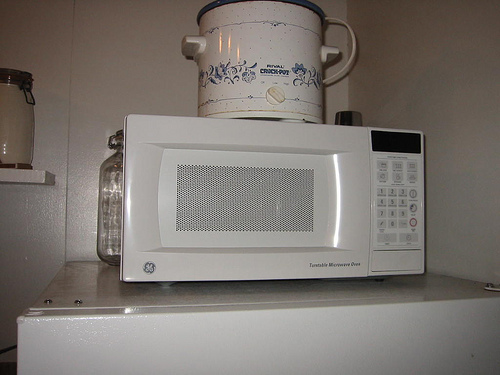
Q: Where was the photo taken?
A: It was taken at the kitchen.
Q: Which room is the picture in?
A: It is at the kitchen.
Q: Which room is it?
A: It is a kitchen.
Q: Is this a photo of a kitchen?
A: Yes, it is showing a kitchen.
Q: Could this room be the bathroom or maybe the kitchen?
A: It is the kitchen.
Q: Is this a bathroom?
A: No, it is a kitchen.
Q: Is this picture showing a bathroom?
A: No, the picture is showing a kitchen.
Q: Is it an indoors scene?
A: Yes, it is indoors.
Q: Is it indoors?
A: Yes, it is indoors.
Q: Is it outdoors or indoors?
A: It is indoors.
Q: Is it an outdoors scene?
A: No, it is indoors.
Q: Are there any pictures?
A: No, there are no pictures.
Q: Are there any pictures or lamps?
A: No, there are no pictures or lamps.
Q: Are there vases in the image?
A: No, there are no vases.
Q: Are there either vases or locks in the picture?
A: No, there are no vases or locks.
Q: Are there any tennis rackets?
A: No, there are no tennis rackets.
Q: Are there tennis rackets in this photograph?
A: No, there are no tennis rackets.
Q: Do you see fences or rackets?
A: No, there are no rackets or fences.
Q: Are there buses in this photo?
A: No, there are no buses.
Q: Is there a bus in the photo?
A: No, there are no buses.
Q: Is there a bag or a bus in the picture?
A: No, there are no buses or bags.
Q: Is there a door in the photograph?
A: Yes, there is a door.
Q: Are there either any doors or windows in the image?
A: Yes, there is a door.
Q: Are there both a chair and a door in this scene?
A: No, there is a door but no chairs.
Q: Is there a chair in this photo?
A: No, there are no chairs.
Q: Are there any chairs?
A: No, there are no chairs.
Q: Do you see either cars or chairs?
A: No, there are no chairs or cars.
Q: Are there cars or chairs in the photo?
A: No, there are no chairs or cars.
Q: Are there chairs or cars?
A: No, there are no chairs or cars.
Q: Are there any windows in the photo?
A: Yes, there is a window.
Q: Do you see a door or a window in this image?
A: Yes, there is a window.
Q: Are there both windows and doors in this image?
A: Yes, there are both a window and a door.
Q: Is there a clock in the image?
A: No, there are no clocks.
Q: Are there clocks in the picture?
A: No, there are no clocks.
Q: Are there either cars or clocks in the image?
A: No, there are no clocks or cars.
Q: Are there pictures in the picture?
A: No, there are no pictures.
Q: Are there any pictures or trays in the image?
A: No, there are no pictures or trays.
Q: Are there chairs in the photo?
A: No, there are no chairs.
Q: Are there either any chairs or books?
A: No, there are no chairs or books.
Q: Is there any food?
A: No, there is no food.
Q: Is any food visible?
A: No, there is no food.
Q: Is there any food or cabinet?
A: No, there are no food or cabinets.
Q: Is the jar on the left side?
A: Yes, the jar is on the left of the image.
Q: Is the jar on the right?
A: No, the jar is on the left of the image.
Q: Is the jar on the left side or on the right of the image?
A: The jar is on the left of the image.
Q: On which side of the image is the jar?
A: The jar is on the left of the image.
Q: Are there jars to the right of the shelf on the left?
A: Yes, there is a jar to the right of the shelf.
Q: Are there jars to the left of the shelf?
A: No, the jar is to the right of the shelf.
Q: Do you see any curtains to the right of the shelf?
A: No, there is a jar to the right of the shelf.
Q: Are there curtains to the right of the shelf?
A: No, there is a jar to the right of the shelf.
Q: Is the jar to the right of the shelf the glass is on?
A: Yes, the jar is to the right of the shelf.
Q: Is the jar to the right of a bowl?
A: No, the jar is to the right of the shelf.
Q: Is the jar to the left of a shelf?
A: No, the jar is to the right of a shelf.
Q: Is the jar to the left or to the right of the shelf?
A: The jar is to the right of the shelf.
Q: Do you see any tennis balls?
A: No, there are no tennis balls.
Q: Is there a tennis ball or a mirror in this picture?
A: No, there are no tennis balls or mirrors.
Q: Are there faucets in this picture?
A: No, there are no faucets.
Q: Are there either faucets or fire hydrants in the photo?
A: No, there are no faucets or fire hydrants.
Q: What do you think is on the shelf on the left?
A: The glass is on the shelf.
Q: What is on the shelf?
A: The glass is on the shelf.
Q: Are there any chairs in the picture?
A: No, there are no chairs.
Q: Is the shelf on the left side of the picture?
A: Yes, the shelf is on the left of the image.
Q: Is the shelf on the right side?
A: No, the shelf is on the left of the image.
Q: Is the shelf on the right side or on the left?
A: The shelf is on the left of the image.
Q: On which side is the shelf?
A: The shelf is on the left of the image.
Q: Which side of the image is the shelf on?
A: The shelf is on the left of the image.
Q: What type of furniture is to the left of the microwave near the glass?
A: The piece of furniture is a shelf.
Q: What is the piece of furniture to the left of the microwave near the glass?
A: The piece of furniture is a shelf.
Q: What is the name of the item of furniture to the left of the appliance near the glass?
A: The piece of furniture is a shelf.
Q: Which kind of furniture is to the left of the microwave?
A: The piece of furniture is a shelf.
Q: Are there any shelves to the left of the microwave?
A: Yes, there is a shelf to the left of the microwave.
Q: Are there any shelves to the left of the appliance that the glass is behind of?
A: Yes, there is a shelf to the left of the microwave.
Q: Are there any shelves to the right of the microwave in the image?
A: No, the shelf is to the left of the microwave.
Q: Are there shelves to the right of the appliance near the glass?
A: No, the shelf is to the left of the microwave.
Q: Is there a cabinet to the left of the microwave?
A: No, there is a shelf to the left of the microwave.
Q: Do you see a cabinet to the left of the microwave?
A: No, there is a shelf to the left of the microwave.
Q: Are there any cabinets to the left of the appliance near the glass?
A: No, there is a shelf to the left of the microwave.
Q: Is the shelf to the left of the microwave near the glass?
A: Yes, the shelf is to the left of the microwave.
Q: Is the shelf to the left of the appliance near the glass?
A: Yes, the shelf is to the left of the microwave.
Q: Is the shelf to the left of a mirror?
A: No, the shelf is to the left of the microwave.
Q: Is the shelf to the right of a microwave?
A: No, the shelf is to the left of a microwave.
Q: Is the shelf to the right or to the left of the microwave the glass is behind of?
A: The shelf is to the left of the microwave.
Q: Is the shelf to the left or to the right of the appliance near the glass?
A: The shelf is to the left of the microwave.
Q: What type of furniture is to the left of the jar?
A: The piece of furniture is a shelf.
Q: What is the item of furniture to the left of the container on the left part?
A: The piece of furniture is a shelf.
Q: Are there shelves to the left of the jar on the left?
A: Yes, there is a shelf to the left of the jar.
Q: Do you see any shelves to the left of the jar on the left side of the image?
A: Yes, there is a shelf to the left of the jar.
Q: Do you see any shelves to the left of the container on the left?
A: Yes, there is a shelf to the left of the jar.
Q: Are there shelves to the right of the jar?
A: No, the shelf is to the left of the jar.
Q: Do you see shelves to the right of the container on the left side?
A: No, the shelf is to the left of the jar.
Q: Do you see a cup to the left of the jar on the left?
A: No, there is a shelf to the left of the jar.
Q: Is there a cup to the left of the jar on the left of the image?
A: No, there is a shelf to the left of the jar.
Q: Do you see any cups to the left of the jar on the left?
A: No, there is a shelf to the left of the jar.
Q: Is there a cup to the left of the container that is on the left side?
A: No, there is a shelf to the left of the jar.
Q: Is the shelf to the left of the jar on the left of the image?
A: Yes, the shelf is to the left of the jar.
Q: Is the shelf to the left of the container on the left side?
A: Yes, the shelf is to the left of the jar.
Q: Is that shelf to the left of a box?
A: No, the shelf is to the left of the jar.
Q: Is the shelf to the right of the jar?
A: No, the shelf is to the left of the jar.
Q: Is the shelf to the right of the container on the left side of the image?
A: No, the shelf is to the left of the jar.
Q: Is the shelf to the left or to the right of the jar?
A: The shelf is to the left of the jar.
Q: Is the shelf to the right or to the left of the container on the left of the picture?
A: The shelf is to the left of the jar.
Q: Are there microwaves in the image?
A: Yes, there is a microwave.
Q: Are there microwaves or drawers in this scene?
A: Yes, there is a microwave.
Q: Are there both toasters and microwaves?
A: No, there is a microwave but no toasters.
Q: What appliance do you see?
A: The appliance is a microwave.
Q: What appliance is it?
A: The appliance is a microwave.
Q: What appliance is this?
A: This is a microwave.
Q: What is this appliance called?
A: This is a microwave.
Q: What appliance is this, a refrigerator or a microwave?
A: This is a microwave.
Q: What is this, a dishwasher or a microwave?
A: This is a microwave.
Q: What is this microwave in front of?
A: The microwave is in front of the glass.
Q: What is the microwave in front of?
A: The microwave is in front of the glass.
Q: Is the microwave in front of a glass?
A: Yes, the microwave is in front of a glass.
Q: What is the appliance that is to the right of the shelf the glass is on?
A: The appliance is a microwave.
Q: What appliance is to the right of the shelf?
A: The appliance is a microwave.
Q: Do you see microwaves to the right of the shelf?
A: Yes, there is a microwave to the right of the shelf.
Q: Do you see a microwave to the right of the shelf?
A: Yes, there is a microwave to the right of the shelf.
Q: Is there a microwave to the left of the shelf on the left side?
A: No, the microwave is to the right of the shelf.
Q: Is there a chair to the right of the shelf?
A: No, there is a microwave to the right of the shelf.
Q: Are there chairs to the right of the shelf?
A: No, there is a microwave to the right of the shelf.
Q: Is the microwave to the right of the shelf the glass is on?
A: Yes, the microwave is to the right of the shelf.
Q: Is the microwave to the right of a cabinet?
A: No, the microwave is to the right of the shelf.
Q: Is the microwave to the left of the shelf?
A: No, the microwave is to the right of the shelf.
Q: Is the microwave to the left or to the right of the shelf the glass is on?
A: The microwave is to the right of the shelf.